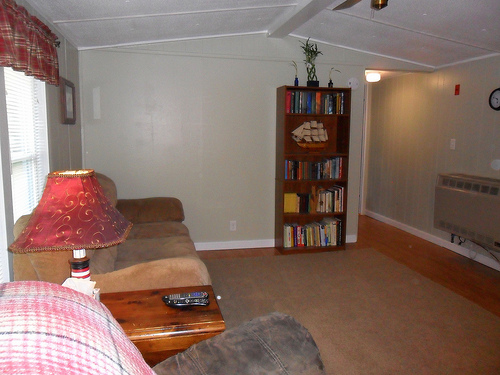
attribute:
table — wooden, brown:
[95, 278, 224, 368]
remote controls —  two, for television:
[162, 288, 212, 314]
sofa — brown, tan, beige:
[12, 167, 212, 300]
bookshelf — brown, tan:
[271, 82, 352, 255]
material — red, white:
[2, 2, 62, 86]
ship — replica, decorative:
[290, 116, 329, 156]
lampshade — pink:
[8, 165, 136, 256]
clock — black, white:
[488, 87, 499, 113]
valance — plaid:
[1, 1, 62, 85]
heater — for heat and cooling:
[432, 167, 499, 259]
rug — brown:
[204, 247, 500, 372]